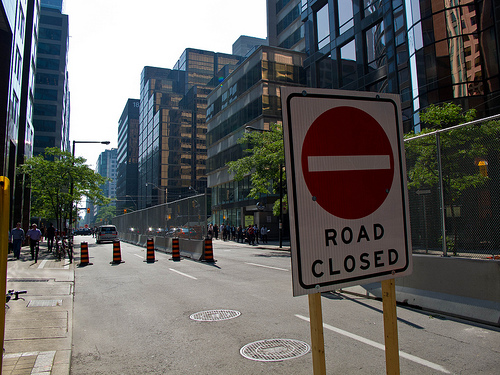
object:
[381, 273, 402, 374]
pole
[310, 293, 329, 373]
pole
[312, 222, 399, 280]
writing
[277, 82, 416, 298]
sign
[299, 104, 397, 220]
circle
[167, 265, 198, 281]
lane marker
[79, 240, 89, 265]
cone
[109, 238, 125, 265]
cone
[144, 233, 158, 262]
cone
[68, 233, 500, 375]
road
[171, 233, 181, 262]
cone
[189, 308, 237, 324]
cover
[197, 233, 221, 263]
barrel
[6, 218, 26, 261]
men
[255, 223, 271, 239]
people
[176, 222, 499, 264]
sidewalk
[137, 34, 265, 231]
building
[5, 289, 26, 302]
handle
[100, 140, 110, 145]
light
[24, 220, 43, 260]
men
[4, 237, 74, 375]
sidewalk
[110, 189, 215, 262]
fence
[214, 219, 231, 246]
people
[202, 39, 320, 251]
building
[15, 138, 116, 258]
tree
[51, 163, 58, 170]
leaves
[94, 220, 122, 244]
car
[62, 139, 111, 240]
lamp